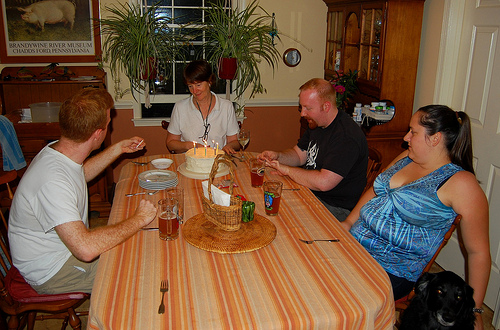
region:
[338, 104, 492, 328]
Woman leaning back in a chair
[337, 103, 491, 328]
Woman petting a dog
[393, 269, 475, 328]
Long haired black dog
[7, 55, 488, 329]
People sitting around a table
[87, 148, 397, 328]
Orange striped tablecloth on a table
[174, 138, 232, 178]
White birthday cake with lit candles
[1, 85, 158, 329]
Red haired man sitting in a brown chair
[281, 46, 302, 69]
Small round wood framed mirror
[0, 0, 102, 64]
Picture of a pig in a wood frame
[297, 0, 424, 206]
Brown wood china cabinet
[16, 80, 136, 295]
red haired man at the table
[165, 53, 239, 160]
woman with white shirt and eyeglasses around her neck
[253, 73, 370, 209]
red haired man with a black shirt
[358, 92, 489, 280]
heavy set lady with dark brown hair and a blue tank top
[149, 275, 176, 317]
fork on the table away from everything else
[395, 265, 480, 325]
black dog sitting on the floor near the lady in blue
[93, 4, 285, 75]
two bushy leaved plants next to the window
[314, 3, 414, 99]
dark wooden hutch against the wall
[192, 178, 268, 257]
brown wicker placemat and napkin holder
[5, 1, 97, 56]
picture with a pig on the wall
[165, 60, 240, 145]
middle-aged woman at her birthday party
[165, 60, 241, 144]
middle-aged Caucasian woman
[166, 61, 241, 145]
middle-aged woman wearing a white polo shirt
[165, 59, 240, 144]
middle-aged woman wearing her reading glasses on a lanyard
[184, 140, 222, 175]
birthday cake with white frosting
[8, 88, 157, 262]
redhead man wearing a white T-shirt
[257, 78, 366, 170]
bearded redhead man wearing a black T-shirt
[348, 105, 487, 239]
brunette woman wearing a blue sleeveless top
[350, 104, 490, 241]
slightly overweight brunette woman wearing a high ponytail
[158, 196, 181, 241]
half full pint of beer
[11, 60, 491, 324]
people sitting at a table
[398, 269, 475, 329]
a black dog sitting next to a woman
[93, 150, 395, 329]
an orange stripe tablecloth on a table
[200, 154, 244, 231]
a wicker basket on a table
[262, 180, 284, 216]
a glass of red juice on a table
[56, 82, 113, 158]
a man with red hair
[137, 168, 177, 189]
a stack of plates on a table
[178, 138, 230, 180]
a birthday cake on a white plate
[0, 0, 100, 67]
a framed poster on a wall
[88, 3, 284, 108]
two green plants hanging from the ceiling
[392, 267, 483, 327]
Black Labrador for family pet.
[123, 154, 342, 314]
Stainless steel utensils laid out on the table cloth.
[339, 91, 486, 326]
Brunette lady with muffintop.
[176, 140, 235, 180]
Birthday cake with white icing and lite candles.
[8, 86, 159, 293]
Red head guy with short hair.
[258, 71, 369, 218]
Man wearing short sleeve black tee shirt.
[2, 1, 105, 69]
Brandywine River Museum Poster in wooden frame.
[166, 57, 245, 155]
Lady that appears to be happy.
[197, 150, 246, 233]
Straw basket with handle for napkins.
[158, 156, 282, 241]
Ice tea with out ice in glasses.